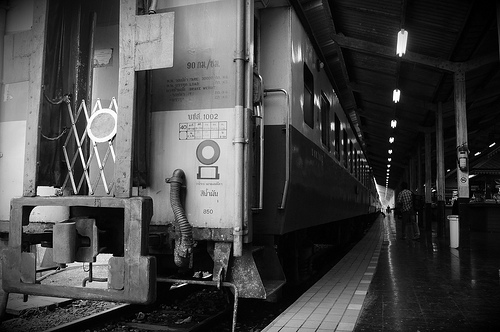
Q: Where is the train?
A: On the rails.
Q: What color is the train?
A: Gray.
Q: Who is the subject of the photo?
A: The train.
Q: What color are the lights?
A: White.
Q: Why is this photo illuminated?
A: Light fixtures.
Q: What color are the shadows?
A: Black.